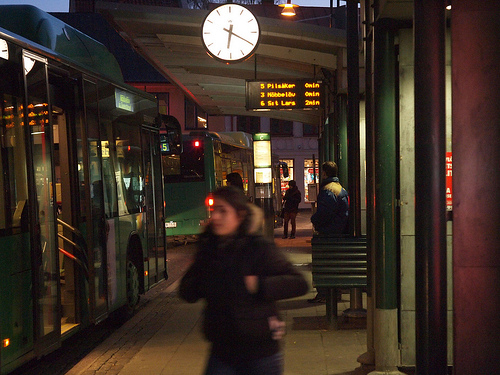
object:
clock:
[199, 3, 258, 63]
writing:
[258, 80, 322, 108]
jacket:
[174, 228, 309, 361]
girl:
[177, 189, 310, 374]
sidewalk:
[72, 222, 371, 375]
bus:
[137, 129, 257, 240]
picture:
[0, 1, 498, 375]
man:
[309, 161, 357, 235]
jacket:
[307, 178, 349, 230]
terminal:
[0, 0, 498, 374]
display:
[249, 132, 273, 211]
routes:
[252, 133, 276, 188]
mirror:
[158, 110, 186, 160]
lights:
[202, 194, 218, 210]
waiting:
[304, 158, 352, 306]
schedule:
[245, 75, 335, 116]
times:
[249, 82, 330, 111]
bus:
[1, 1, 182, 372]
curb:
[59, 203, 194, 373]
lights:
[190, 135, 215, 210]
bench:
[308, 224, 370, 326]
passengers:
[278, 177, 301, 240]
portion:
[205, 47, 245, 64]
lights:
[276, 155, 320, 202]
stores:
[272, 138, 329, 214]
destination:
[111, 88, 141, 112]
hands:
[235, 275, 267, 292]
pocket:
[224, 267, 258, 301]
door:
[22, 48, 99, 348]